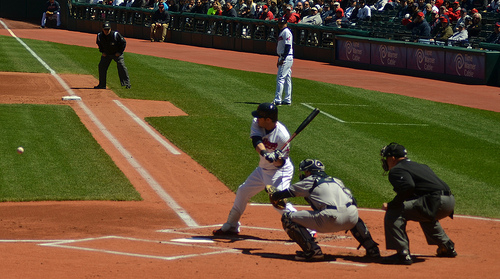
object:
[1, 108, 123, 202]
grass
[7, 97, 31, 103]
dirt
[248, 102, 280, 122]
helmet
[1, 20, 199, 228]
line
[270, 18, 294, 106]
man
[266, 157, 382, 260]
catcher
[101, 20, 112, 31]
hat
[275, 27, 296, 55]
shirt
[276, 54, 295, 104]
pants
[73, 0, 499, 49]
crowd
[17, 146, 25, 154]
baseball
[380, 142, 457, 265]
umpire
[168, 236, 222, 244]
home-plate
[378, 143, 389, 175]
facemask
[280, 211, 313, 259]
shinguard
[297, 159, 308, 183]
facemask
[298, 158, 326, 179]
helmet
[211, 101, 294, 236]
batter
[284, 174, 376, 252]
uniform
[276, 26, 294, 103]
uniform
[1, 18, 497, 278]
field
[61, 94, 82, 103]
1st base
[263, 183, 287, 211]
glove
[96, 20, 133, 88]
umpire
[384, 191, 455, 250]
pants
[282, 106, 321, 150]
bat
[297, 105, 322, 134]
tip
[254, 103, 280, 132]
head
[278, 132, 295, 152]
handle